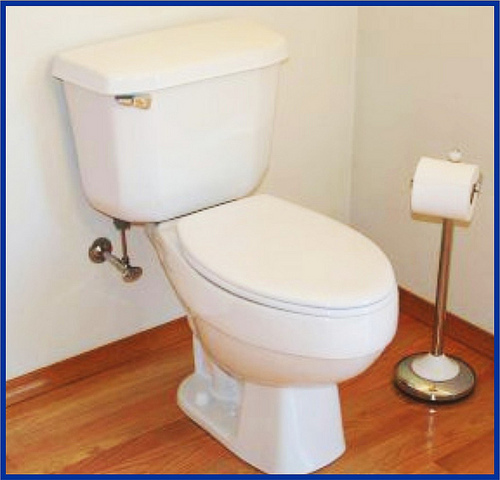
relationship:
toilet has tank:
[54, 17, 433, 454] [44, 18, 290, 230]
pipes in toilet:
[85, 215, 137, 272] [51, 24, 401, 479]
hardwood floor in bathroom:
[16, 361, 246, 476] [13, 14, 488, 469]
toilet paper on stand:
[409, 151, 481, 223] [393, 146, 479, 406]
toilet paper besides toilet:
[409, 151, 481, 223] [51, 24, 401, 479]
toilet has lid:
[51, 24, 401, 479] [175, 192, 397, 312]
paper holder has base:
[394, 217, 476, 402] [405, 350, 467, 383]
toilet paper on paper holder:
[409, 151, 482, 225] [394, 217, 476, 402]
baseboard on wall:
[8, 317, 188, 421] [352, 9, 497, 334]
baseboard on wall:
[404, 284, 498, 364] [2, 6, 350, 383]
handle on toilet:
[114, 90, 155, 112] [51, 24, 401, 479]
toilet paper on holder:
[409, 151, 482, 225] [388, 143, 488, 408]